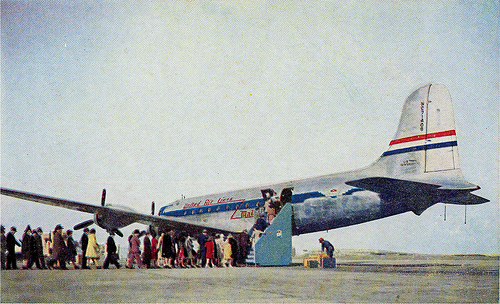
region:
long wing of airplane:
[0, 187, 252, 241]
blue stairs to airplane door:
[239, 202, 293, 267]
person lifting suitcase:
[316, 236, 337, 266]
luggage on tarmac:
[301, 252, 336, 268]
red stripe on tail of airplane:
[384, 130, 455, 145]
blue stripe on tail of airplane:
[373, 140, 457, 157]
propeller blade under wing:
[73, 220, 97, 230]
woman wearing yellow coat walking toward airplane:
[85, 228, 100, 269]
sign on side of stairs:
[274, 228, 282, 238]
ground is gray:
[1, 253, 498, 302]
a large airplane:
[1, 77, 489, 243]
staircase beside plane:
[230, 188, 297, 274]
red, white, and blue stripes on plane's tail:
[371, 82, 474, 170]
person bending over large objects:
[295, 228, 355, 280]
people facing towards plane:
[2, 185, 244, 279]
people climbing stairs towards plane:
[242, 180, 287, 265]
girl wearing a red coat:
[201, 233, 218, 268]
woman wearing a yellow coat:
[81, 220, 103, 272]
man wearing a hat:
[47, 218, 68, 244]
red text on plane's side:
[171, 188, 246, 216]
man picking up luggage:
[312, 236, 337, 265]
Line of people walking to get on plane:
[7, 222, 249, 271]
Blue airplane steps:
[245, 204, 292, 266]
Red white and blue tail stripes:
[383, 129, 460, 151]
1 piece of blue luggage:
[320, 255, 338, 267]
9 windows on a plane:
[180, 199, 263, 216]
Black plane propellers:
[70, 188, 125, 239]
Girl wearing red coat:
[204, 235, 213, 266]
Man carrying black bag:
[104, 230, 121, 266]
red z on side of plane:
[227, 195, 247, 220]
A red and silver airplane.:
[5, 82, 491, 242]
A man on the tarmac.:
[318, 237, 335, 259]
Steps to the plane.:
[243, 201, 293, 266]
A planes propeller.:
[72, 187, 138, 238]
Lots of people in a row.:
[0, 223, 250, 270]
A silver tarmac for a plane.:
[1, 257, 499, 302]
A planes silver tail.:
[375, 80, 462, 175]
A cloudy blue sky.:
[2, 1, 497, 256]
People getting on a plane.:
[237, 187, 294, 266]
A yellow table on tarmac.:
[305, 252, 327, 267]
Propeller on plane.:
[81, 182, 146, 244]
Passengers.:
[178, 176, 305, 273]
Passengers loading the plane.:
[54, 177, 477, 279]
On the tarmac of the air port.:
[56, 180, 266, 299]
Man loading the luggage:
[305, 233, 368, 279]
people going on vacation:
[50, 229, 152, 260]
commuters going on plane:
[101, 182, 295, 297]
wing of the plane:
[58, 165, 315, 295]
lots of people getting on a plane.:
[22, 204, 291, 295]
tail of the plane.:
[334, 74, 476, 301]